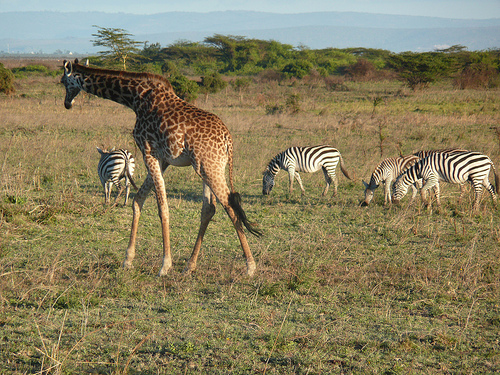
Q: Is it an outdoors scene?
A: Yes, it is outdoors.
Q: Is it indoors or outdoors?
A: It is outdoors.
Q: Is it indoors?
A: No, it is outdoors.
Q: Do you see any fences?
A: No, there are no fences.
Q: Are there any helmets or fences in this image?
A: No, there are no fences or helmets.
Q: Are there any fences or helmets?
A: No, there are no fences or helmets.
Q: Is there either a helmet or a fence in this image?
A: No, there are no fences or helmets.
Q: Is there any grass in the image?
A: Yes, there is grass.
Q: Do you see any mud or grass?
A: Yes, there is grass.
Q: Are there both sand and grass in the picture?
A: No, there is grass but no sand.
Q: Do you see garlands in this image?
A: No, there are no garlands.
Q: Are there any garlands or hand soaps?
A: No, there are no garlands or hand soaps.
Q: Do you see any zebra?
A: Yes, there is a zebra.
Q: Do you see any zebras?
A: Yes, there is a zebra.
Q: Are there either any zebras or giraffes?
A: Yes, there is a zebra.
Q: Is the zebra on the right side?
A: Yes, the zebra is on the right of the image.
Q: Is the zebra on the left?
A: No, the zebra is on the right of the image.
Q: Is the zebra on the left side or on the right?
A: The zebra is on the right of the image.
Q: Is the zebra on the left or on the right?
A: The zebra is on the right of the image.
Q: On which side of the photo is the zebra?
A: The zebra is on the right of the image.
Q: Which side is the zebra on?
A: The zebra is on the right of the image.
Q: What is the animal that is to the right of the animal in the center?
A: The animal is a zebra.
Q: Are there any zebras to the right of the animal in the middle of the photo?
A: Yes, there is a zebra to the right of the animal.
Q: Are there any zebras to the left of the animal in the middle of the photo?
A: No, the zebra is to the right of the animal.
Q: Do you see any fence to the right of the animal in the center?
A: No, there is a zebra to the right of the animal.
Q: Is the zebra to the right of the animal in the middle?
A: Yes, the zebra is to the right of the animal.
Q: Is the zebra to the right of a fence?
A: No, the zebra is to the right of the animal.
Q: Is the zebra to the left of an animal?
A: No, the zebra is to the right of an animal.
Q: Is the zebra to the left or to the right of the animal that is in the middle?
A: The zebra is to the right of the animal.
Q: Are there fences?
A: No, there are no fences.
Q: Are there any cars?
A: No, there are no cars.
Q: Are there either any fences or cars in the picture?
A: No, there are no cars or fences.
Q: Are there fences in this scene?
A: No, there are no fences.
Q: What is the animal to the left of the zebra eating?
A: The animal is eating grass.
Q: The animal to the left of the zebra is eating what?
A: The animal is eating grass.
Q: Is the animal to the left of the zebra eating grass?
A: Yes, the animal is eating grass.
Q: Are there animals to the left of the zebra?
A: Yes, there is an animal to the left of the zebra.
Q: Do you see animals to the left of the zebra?
A: Yes, there is an animal to the left of the zebra.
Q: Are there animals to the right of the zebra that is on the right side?
A: No, the animal is to the left of the zebra.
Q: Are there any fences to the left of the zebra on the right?
A: No, there is an animal to the left of the zebra.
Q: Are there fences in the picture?
A: No, there are no fences.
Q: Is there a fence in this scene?
A: No, there are no fences.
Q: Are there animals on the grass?
A: Yes, there is an animal on the grass.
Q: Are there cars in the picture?
A: No, there are no cars.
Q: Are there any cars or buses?
A: No, there are no cars or buses.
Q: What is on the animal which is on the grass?
A: The spots are on the animal.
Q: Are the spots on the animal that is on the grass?
A: Yes, the spots are on the animal.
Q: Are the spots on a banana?
A: No, the spots are on the animal.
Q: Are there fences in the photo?
A: No, there are no fences.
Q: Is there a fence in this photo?
A: No, there are no fences.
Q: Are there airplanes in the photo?
A: No, there are no airplanes.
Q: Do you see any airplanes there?
A: No, there are no airplanes.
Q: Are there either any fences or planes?
A: No, there are no planes or fences.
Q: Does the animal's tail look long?
A: Yes, the tail is long.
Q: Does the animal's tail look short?
A: No, the tail is long.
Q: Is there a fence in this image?
A: No, there are no fences.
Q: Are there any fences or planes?
A: No, there are no fences or planes.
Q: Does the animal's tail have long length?
A: Yes, the tail is long.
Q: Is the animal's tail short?
A: No, the tail is long.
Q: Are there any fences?
A: No, there are no fences.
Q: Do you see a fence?
A: No, there are no fences.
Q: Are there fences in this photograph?
A: No, there are no fences.